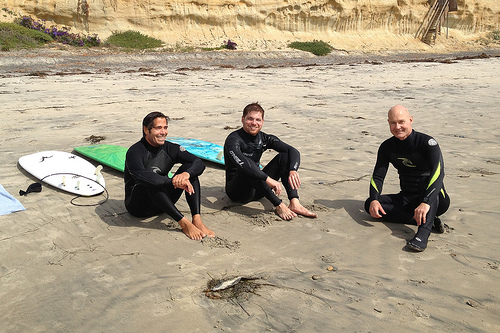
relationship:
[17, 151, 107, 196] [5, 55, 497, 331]
board on beach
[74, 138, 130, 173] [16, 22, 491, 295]
surf board on beach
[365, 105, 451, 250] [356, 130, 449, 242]
man in wetsuit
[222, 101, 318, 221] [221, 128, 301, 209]
man in swim suit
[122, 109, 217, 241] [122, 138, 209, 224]
man in swim suit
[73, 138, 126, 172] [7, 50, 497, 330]
surf board on ground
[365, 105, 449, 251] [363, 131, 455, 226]
man wearing swim suit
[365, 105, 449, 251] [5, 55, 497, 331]
man on beach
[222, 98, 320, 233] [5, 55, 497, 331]
man sitting on beach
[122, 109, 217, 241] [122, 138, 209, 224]
man wearing swim suit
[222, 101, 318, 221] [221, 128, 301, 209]
man wearing swim suit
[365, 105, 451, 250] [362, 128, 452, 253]
man wearing swim suit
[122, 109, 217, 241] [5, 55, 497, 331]
man sitting on beach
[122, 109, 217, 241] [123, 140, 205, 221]
man wearing suit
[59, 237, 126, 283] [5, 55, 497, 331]
sand on beach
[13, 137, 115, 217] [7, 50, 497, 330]
board on ground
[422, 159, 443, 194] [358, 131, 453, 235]
stripe on wetsuit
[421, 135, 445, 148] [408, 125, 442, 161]
decal on shoulder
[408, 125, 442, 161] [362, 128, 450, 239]
shoulder of swim suit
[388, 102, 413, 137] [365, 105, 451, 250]
head of man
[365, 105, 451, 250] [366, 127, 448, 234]
man wearing wetsuit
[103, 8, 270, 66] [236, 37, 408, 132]
cliff behind beach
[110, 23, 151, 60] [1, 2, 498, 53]
plants at base of cliff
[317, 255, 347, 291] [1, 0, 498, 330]
rock on beach